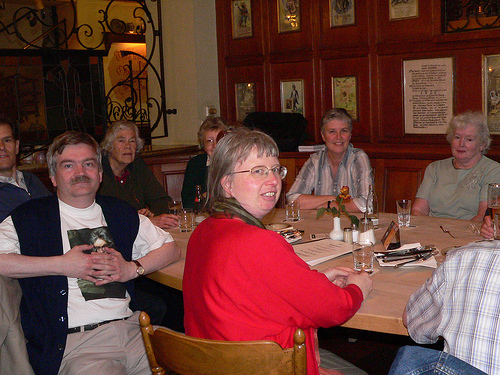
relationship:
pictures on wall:
[245, 7, 495, 134] [213, 1, 498, 217]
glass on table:
[385, 197, 422, 229] [121, 165, 499, 329]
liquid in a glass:
[395, 208, 413, 228] [395, 197, 412, 229]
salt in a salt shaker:
[351, 218, 377, 275] [358, 205, 376, 251]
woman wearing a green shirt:
[412, 110, 498, 223] [419, 155, 498, 220]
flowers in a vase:
[328, 183, 353, 218] [328, 216, 344, 241]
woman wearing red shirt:
[172, 118, 347, 373] [180, 229, 360, 353]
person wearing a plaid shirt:
[399, 229, 499, 366] [439, 284, 499, 375]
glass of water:
[398, 200, 409, 225] [360, 227, 418, 312]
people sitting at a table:
[5, 209, 495, 348] [124, 196, 496, 355]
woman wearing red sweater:
[182, 128, 374, 373] [177, 213, 362, 373]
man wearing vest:
[28, 136, 166, 372] [5, 201, 163, 328]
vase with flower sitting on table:
[328, 217, 343, 243] [352, 200, 454, 353]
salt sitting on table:
[351, 218, 377, 275] [352, 198, 444, 372]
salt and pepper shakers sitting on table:
[351, 214, 381, 308] [362, 264, 406, 351]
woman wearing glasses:
[182, 128, 374, 373] [224, 162, 290, 179]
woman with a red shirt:
[182, 128, 374, 373] [183, 213, 365, 375]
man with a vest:
[0, 130, 182, 375] [10, 193, 139, 373]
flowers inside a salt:
[316, 186, 360, 229] [351, 218, 377, 275]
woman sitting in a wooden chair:
[182, 128, 374, 373] [138, 310, 310, 374]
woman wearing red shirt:
[182, 128, 374, 373] [183, 213, 365, 375]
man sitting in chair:
[0, 130, 182, 375] [0, 251, 115, 364]